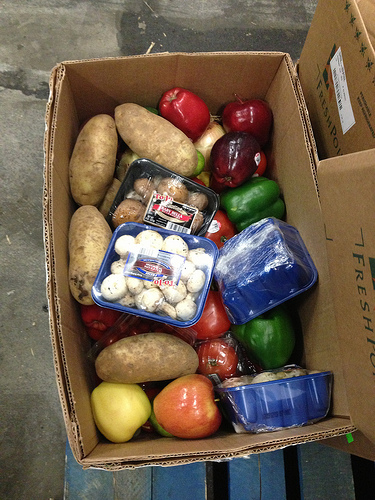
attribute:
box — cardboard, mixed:
[45, 50, 358, 465]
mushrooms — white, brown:
[94, 218, 218, 316]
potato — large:
[115, 103, 202, 169]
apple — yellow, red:
[160, 89, 212, 135]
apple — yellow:
[90, 383, 151, 439]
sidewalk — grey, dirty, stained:
[3, 4, 374, 496]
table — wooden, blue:
[52, 434, 358, 498]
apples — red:
[156, 87, 267, 186]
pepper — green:
[218, 178, 287, 231]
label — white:
[136, 255, 176, 289]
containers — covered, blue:
[100, 159, 315, 330]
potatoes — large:
[53, 101, 209, 379]